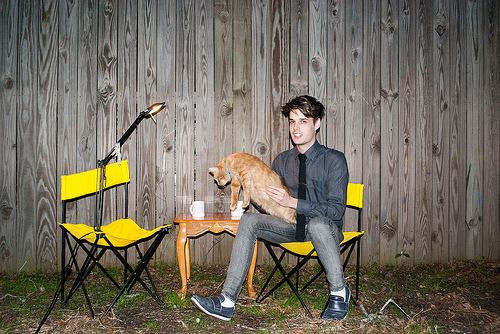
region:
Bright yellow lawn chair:
[23, 131, 187, 321]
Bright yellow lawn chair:
[260, 137, 396, 299]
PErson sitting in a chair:
[212, 86, 367, 296]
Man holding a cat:
[213, 50, 348, 327]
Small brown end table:
[167, 186, 271, 303]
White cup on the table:
[182, 190, 207, 227]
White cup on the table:
[220, 186, 250, 221]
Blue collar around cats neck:
[211, 151, 238, 182]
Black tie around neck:
[283, 147, 318, 248]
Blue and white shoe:
[163, 283, 257, 330]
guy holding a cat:
[183, 70, 380, 322]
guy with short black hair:
[183, 87, 368, 329]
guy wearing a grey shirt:
[180, 90, 371, 321]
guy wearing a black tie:
[186, 73, 380, 329]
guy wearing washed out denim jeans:
[178, 83, 404, 333]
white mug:
[177, 194, 212, 224]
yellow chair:
[17, 130, 185, 313]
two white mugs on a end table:
[171, 178, 270, 312]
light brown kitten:
[197, 150, 307, 221]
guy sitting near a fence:
[183, 74, 402, 331]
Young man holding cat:
[192, 91, 358, 325]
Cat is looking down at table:
[208, 147, 303, 224]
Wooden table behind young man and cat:
[170, 205, 265, 300]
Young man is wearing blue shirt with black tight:
[268, 146, 352, 238]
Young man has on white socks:
[219, 289, 237, 307]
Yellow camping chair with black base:
[50, 157, 178, 316]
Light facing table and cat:
[71, 98, 169, 313]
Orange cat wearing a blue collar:
[208, 147, 299, 228]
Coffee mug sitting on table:
[183, 198, 209, 220]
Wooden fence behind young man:
[0, 2, 496, 267]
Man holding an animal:
[189, 86, 377, 318]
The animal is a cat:
[205, 155, 313, 225]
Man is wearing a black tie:
[288, 144, 315, 237]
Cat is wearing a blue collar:
[208, 154, 236, 181]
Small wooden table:
[161, 193, 275, 295]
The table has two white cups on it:
[156, 182, 271, 288]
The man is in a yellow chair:
[246, 92, 391, 308]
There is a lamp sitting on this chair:
[66, 94, 191, 259]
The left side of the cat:
[198, 135, 288, 223]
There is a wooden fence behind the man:
[163, 4, 458, 290]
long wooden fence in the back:
[359, 53, 470, 182]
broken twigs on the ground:
[357, 297, 417, 318]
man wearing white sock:
[310, 282, 347, 297]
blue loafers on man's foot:
[310, 284, 358, 326]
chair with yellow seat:
[3, 157, 185, 259]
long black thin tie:
[291, 151, 313, 238]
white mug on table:
[181, 193, 212, 223]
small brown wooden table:
[159, 203, 265, 294]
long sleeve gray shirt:
[263, 144, 369, 240]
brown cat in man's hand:
[212, 148, 304, 220]